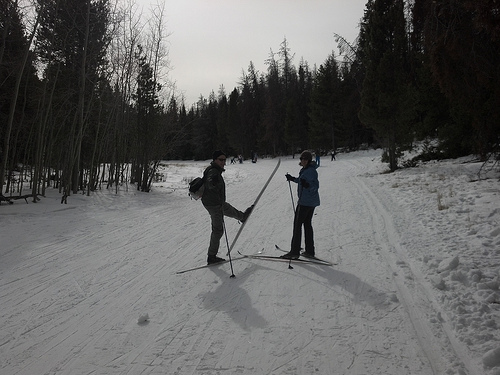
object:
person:
[201, 150, 253, 265]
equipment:
[175, 159, 281, 278]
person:
[280, 151, 319, 259]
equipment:
[238, 166, 336, 266]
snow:
[0, 161, 499, 374]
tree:
[346, 0, 422, 174]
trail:
[336, 159, 486, 374]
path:
[1, 161, 487, 374]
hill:
[1, 124, 499, 374]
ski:
[226, 157, 281, 256]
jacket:
[294, 160, 320, 205]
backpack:
[188, 177, 206, 201]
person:
[315, 149, 321, 167]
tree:
[72, 1, 91, 197]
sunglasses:
[217, 157, 227, 161]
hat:
[299, 150, 312, 160]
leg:
[207, 208, 225, 261]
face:
[215, 155, 226, 167]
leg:
[282, 205, 306, 260]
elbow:
[206, 184, 216, 193]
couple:
[201, 151, 320, 264]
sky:
[105, 3, 355, 79]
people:
[328, 149, 340, 161]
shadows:
[292, 255, 401, 316]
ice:
[137, 313, 149, 325]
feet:
[207, 254, 226, 263]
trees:
[30, 0, 112, 196]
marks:
[16, 257, 123, 323]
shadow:
[203, 264, 273, 332]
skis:
[237, 249, 335, 267]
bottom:
[0, 133, 500, 205]